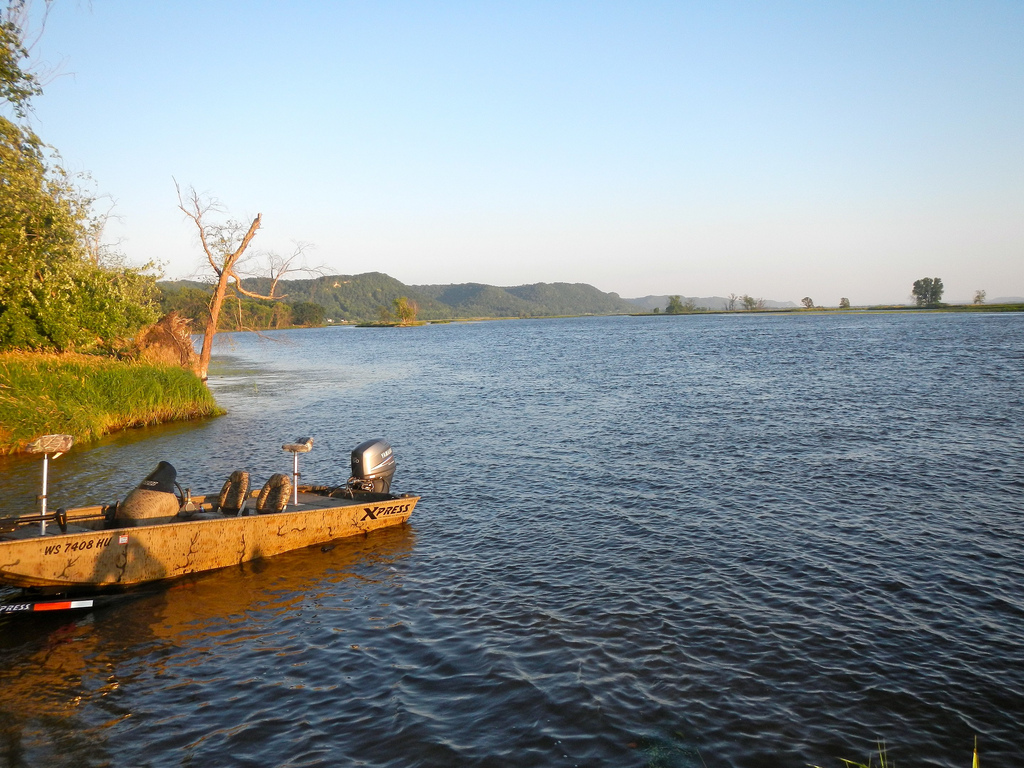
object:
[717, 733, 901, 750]
van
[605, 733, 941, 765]
van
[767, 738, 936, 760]
van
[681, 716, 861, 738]
van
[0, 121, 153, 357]
bush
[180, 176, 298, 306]
branches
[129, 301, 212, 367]
trunk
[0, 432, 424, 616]
boat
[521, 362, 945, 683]
body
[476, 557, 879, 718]
ripples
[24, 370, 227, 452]
shore line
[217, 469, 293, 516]
seats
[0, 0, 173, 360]
trees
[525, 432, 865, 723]
water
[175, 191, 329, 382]
tree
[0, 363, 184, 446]
grass